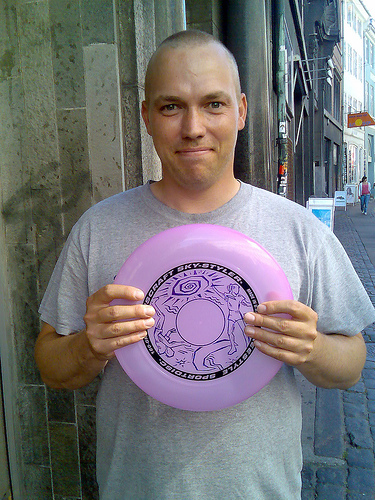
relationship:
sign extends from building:
[348, 107, 371, 130] [303, 3, 349, 219]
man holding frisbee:
[34, 28, 370, 494] [107, 222, 293, 414]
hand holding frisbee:
[241, 300, 318, 361] [107, 222, 293, 414]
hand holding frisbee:
[87, 282, 163, 350] [107, 222, 293, 414]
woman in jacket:
[354, 175, 372, 212] [340, 177, 372, 212]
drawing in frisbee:
[155, 268, 237, 403] [69, 213, 334, 418]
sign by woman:
[348, 107, 375, 130] [356, 172, 370, 214]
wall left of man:
[3, 2, 160, 499] [34, 28, 370, 494]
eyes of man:
[157, 98, 226, 114] [34, 28, 370, 494]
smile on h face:
[171, 137, 219, 167] [146, 34, 238, 190]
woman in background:
[354, 175, 372, 215] [264, 41, 374, 272]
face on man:
[146, 34, 238, 190] [34, 28, 370, 494]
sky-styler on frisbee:
[174, 257, 243, 285] [107, 222, 293, 414]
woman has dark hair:
[354, 175, 372, 215] [358, 176, 368, 183]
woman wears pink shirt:
[354, 175, 372, 215] [360, 180, 371, 197]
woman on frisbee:
[209, 283, 252, 355] [107, 222, 293, 414]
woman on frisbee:
[150, 296, 191, 358] [107, 222, 293, 414]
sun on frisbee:
[183, 263, 210, 299] [107, 222, 293, 414]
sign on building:
[348, 107, 375, 130] [323, 1, 347, 208]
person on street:
[357, 175, 369, 215] [300, 194, 372, 497]